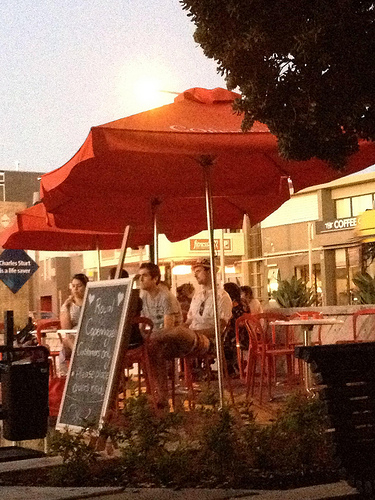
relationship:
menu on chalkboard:
[60, 275, 122, 448] [49, 275, 135, 446]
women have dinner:
[177, 280, 264, 377] [142, 308, 187, 333]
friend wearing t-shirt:
[139, 262, 183, 395] [141, 289, 182, 327]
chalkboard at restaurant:
[46, 260, 147, 446] [1, 91, 370, 451]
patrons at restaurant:
[58, 255, 264, 411] [1, 91, 370, 451]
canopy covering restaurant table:
[39, 87, 375, 243] [39, 310, 198, 372]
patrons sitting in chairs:
[58, 255, 264, 411] [167, 310, 237, 415]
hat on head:
[189, 254, 216, 268] [190, 267, 216, 285]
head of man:
[190, 267, 216, 285] [166, 247, 234, 369]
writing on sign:
[0, 256, 40, 276] [0, 249, 40, 293]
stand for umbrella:
[194, 157, 229, 421] [34, 87, 374, 227]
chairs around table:
[237, 307, 373, 405] [267, 316, 345, 403]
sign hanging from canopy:
[0, 247, 63, 294] [44, 85, 292, 194]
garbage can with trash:
[2, 342, 54, 459] [10, 354, 33, 367]